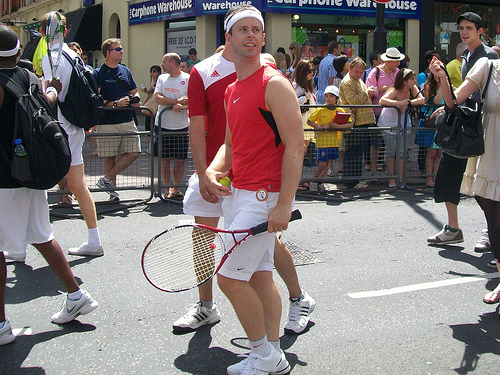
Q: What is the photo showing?
A: It is showing a street.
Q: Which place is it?
A: It is a street.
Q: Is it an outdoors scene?
A: Yes, it is outdoors.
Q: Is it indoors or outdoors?
A: It is outdoors.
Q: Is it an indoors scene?
A: No, it is outdoors.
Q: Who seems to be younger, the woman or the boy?
A: The boy is younger than the woman.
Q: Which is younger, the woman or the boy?
A: The boy is younger than the woman.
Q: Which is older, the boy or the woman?
A: The woman is older than the boy.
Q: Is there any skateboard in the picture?
A: No, there are no skateboards.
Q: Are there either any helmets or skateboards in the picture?
A: No, there are no skateboards or helmets.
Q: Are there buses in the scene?
A: No, there are no buses.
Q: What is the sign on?
A: The sign is on the building.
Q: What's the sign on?
A: The sign is on the building.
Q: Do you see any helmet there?
A: No, there are no helmets.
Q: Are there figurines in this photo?
A: No, there are no figurines.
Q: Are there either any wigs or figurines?
A: No, there are no figurines or wigs.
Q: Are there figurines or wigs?
A: No, there are no figurines or wigs.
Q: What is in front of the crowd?
A: The barrier is in front of the crowd.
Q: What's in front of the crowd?
A: The barrier is in front of the crowd.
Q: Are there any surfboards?
A: No, there are no surfboards.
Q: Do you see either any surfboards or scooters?
A: No, there are no surfboards or scooters.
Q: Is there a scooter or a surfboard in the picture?
A: No, there are no surfboards or scooters.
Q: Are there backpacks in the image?
A: Yes, there is a backpack.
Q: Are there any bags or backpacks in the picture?
A: Yes, there is a backpack.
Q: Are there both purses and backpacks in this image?
A: Yes, there are both a backpack and a purse.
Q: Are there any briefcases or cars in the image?
A: No, there are no cars or briefcases.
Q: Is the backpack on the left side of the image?
A: Yes, the backpack is on the left of the image.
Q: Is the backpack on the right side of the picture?
A: No, the backpack is on the left of the image.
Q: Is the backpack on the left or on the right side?
A: The backpack is on the left of the image.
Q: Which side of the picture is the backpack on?
A: The backpack is on the left of the image.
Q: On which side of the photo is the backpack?
A: The backpack is on the left of the image.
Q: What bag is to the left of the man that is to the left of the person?
A: The bag is a backpack.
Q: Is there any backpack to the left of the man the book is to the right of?
A: Yes, there is a backpack to the left of the man.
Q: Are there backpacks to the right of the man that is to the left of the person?
A: No, the backpack is to the left of the man.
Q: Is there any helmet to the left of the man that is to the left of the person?
A: No, there is a backpack to the left of the man.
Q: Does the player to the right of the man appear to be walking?
A: Yes, the player is walking.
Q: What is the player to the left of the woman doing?
A: The player is walking.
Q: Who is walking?
A: The player is walking.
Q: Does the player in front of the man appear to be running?
A: No, the player is walking.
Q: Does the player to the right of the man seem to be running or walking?
A: The player is walking.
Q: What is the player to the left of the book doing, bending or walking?
A: The player is walking.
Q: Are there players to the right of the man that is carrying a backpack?
A: Yes, there is a player to the right of the man.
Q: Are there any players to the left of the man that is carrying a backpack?
A: No, the player is to the right of the man.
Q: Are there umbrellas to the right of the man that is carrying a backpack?
A: No, there is a player to the right of the man.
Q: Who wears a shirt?
A: The player wears a shirt.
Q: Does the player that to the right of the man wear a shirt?
A: Yes, the player wears a shirt.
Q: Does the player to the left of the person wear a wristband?
A: No, the player wears a shirt.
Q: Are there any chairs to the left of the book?
A: No, there is a player to the left of the book.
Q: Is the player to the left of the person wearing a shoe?
A: Yes, the player is wearing a shoe.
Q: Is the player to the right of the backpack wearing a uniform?
A: No, the player is wearing a shoe.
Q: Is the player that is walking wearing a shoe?
A: Yes, the player is wearing a shoe.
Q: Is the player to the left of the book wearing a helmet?
A: No, the player is wearing a shoe.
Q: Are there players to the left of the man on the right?
A: Yes, there is a player to the left of the man.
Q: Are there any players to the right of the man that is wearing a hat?
A: No, the player is to the left of the man.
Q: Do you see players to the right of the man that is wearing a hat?
A: No, the player is to the left of the man.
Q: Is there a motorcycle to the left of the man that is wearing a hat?
A: No, there is a player to the left of the man.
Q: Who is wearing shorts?
A: The player is wearing shorts.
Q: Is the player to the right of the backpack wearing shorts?
A: Yes, the player is wearing shorts.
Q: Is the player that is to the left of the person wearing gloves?
A: No, the player is wearing shorts.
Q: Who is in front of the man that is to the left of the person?
A: The player is in front of the man.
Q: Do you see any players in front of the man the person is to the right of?
A: Yes, there is a player in front of the man.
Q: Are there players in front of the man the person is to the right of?
A: Yes, there is a player in front of the man.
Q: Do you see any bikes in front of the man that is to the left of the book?
A: No, there is a player in front of the man.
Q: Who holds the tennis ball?
A: The player holds the tennis ball.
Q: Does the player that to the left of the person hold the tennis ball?
A: Yes, the player holds the tennis ball.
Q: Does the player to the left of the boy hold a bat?
A: No, the player holds the tennis ball.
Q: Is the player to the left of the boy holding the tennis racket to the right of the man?
A: Yes, the player is holding the tennis racket.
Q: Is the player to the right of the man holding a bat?
A: No, the player is holding the tennis racket.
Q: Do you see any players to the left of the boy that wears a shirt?
A: Yes, there is a player to the left of the boy.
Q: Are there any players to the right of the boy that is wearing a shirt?
A: No, the player is to the left of the boy.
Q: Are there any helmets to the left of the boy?
A: No, there is a player to the left of the boy.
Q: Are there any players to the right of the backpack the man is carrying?
A: Yes, there is a player to the right of the backpack.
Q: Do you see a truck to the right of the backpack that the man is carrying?
A: No, there is a player to the right of the backpack.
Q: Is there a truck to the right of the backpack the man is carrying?
A: No, there is a player to the right of the backpack.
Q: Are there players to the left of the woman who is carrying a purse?
A: Yes, there is a player to the left of the woman.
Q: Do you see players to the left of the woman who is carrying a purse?
A: Yes, there is a player to the left of the woman.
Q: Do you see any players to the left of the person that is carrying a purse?
A: Yes, there is a player to the left of the woman.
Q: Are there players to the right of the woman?
A: No, the player is to the left of the woman.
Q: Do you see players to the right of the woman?
A: No, the player is to the left of the woman.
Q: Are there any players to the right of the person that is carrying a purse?
A: No, the player is to the left of the woman.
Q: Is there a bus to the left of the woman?
A: No, there is a player to the left of the woman.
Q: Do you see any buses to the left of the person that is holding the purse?
A: No, there is a player to the left of the woman.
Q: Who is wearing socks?
A: The player is wearing socks.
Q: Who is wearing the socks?
A: The player is wearing socks.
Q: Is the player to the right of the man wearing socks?
A: Yes, the player is wearing socks.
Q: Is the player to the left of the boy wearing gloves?
A: No, the player is wearing socks.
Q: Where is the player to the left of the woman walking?
A: The player is walking on the street.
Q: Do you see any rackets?
A: Yes, there is a racket.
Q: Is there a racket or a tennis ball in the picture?
A: Yes, there is a racket.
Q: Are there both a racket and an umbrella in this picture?
A: No, there is a racket but no umbrellas.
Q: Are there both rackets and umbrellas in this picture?
A: No, there is a racket but no umbrellas.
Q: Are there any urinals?
A: No, there are no urinals.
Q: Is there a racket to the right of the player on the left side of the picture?
A: Yes, there is a racket to the right of the player.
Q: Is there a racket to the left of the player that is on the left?
A: No, the racket is to the right of the player.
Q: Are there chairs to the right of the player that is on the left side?
A: No, there is a racket to the right of the player.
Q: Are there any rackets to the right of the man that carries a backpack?
A: Yes, there is a racket to the right of the man.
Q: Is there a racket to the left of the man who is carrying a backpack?
A: No, the racket is to the right of the man.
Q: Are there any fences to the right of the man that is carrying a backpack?
A: No, there is a racket to the right of the man.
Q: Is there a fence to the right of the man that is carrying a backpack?
A: No, there is a racket to the right of the man.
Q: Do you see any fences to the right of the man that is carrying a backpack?
A: No, there is a racket to the right of the man.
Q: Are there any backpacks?
A: Yes, there is a backpack.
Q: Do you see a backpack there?
A: Yes, there is a backpack.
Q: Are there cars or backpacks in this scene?
A: Yes, there is a backpack.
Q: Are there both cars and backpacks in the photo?
A: No, there is a backpack but no cars.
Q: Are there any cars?
A: No, there are no cars.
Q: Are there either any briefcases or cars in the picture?
A: No, there are no cars or briefcases.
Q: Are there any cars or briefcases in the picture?
A: No, there are no cars or briefcases.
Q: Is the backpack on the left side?
A: Yes, the backpack is on the left of the image.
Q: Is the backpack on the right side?
A: No, the backpack is on the left of the image.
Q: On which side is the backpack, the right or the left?
A: The backpack is on the left of the image.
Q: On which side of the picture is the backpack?
A: The backpack is on the left of the image.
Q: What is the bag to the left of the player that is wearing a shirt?
A: The bag is a backpack.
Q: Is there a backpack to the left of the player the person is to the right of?
A: Yes, there is a backpack to the left of the player.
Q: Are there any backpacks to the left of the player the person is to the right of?
A: Yes, there is a backpack to the left of the player.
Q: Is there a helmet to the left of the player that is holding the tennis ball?
A: No, there is a backpack to the left of the player.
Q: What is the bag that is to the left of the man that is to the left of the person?
A: The bag is a backpack.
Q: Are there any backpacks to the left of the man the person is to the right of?
A: Yes, there is a backpack to the left of the man.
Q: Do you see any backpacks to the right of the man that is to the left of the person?
A: No, the backpack is to the left of the man.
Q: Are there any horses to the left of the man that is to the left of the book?
A: No, there is a backpack to the left of the man.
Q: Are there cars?
A: No, there are no cars.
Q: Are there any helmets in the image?
A: No, there are no helmets.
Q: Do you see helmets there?
A: No, there are no helmets.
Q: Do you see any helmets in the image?
A: No, there are no helmets.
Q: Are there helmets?
A: No, there are no helmets.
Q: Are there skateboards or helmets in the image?
A: No, there are no helmets or skateboards.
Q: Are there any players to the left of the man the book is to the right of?
A: Yes, there is a player to the left of the man.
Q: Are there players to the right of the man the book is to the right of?
A: No, the player is to the left of the man.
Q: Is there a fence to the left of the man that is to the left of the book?
A: No, there is a player to the left of the man.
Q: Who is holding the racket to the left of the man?
A: The player is holding the tennis racket.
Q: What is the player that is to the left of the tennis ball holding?
A: The player is holding the racket.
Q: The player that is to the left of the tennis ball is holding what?
A: The player is holding the racket.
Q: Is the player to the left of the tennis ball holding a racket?
A: Yes, the player is holding a racket.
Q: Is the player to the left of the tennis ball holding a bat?
A: No, the player is holding a racket.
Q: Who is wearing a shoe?
A: The player is wearing a shoe.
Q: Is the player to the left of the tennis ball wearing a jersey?
A: No, the player is wearing a shoe.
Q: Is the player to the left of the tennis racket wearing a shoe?
A: Yes, the player is wearing a shoe.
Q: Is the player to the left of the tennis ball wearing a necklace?
A: No, the player is wearing a shoe.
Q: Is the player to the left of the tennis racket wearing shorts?
A: Yes, the player is wearing shorts.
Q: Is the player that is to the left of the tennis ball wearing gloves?
A: No, the player is wearing shorts.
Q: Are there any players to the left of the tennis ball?
A: Yes, there is a player to the left of the tennis ball.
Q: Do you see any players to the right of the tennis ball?
A: No, the player is to the left of the tennis ball.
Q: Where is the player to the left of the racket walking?
A: The player is walking on the street.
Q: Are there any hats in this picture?
A: Yes, there is a hat.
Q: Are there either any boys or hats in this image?
A: Yes, there is a hat.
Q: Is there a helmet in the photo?
A: No, there are no helmets.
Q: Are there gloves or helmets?
A: No, there are no helmets or gloves.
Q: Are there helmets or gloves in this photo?
A: No, there are no helmets or gloves.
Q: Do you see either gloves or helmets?
A: No, there are no helmets or gloves.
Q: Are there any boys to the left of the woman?
A: Yes, there is a boy to the left of the woman.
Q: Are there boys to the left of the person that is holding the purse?
A: Yes, there is a boy to the left of the woman.